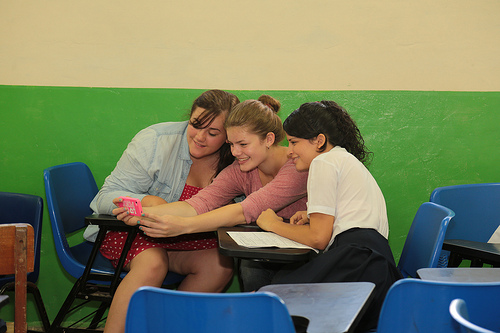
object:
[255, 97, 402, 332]
smiling woman